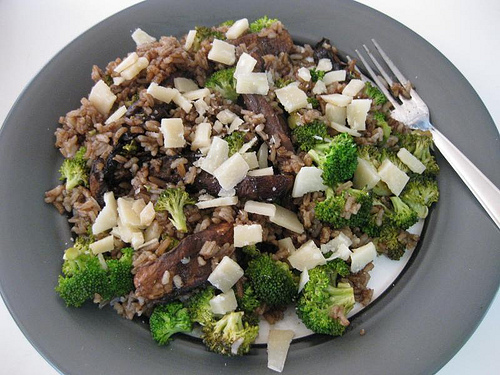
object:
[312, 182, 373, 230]
broccoli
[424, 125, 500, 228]
handle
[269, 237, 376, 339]
piece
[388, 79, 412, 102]
food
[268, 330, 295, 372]
onion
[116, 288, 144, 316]
rice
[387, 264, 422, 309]
accent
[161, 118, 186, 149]
cheese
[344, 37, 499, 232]
fork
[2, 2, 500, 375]
plate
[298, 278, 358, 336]
broccoli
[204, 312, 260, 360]
broccoli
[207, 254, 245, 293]
cheese flake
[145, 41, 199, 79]
rice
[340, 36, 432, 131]
prongs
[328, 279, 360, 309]
stalk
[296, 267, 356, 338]
broccoli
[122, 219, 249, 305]
meat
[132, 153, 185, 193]
rice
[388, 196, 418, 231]
broccoli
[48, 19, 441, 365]
dinner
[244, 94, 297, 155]
beef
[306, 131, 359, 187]
broccoli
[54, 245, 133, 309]
broccoli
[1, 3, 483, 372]
table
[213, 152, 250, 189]
cheese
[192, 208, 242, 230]
rice